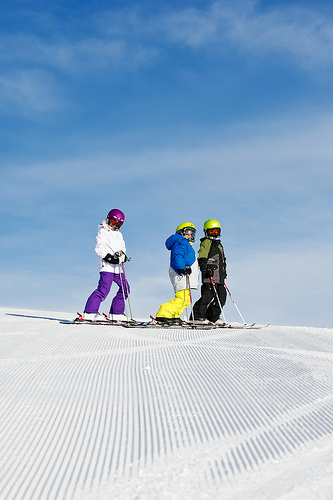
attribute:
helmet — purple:
[108, 209, 125, 229]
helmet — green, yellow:
[204, 219, 223, 233]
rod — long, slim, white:
[117, 261, 130, 324]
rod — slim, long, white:
[123, 267, 142, 319]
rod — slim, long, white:
[184, 275, 196, 327]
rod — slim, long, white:
[211, 276, 230, 325]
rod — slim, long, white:
[223, 280, 252, 325]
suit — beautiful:
[191, 237, 227, 321]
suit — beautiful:
[154, 233, 199, 319]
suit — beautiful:
[83, 222, 130, 318]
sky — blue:
[0, 0, 332, 330]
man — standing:
[189, 219, 228, 323]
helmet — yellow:
[179, 221, 197, 235]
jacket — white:
[95, 222, 129, 274]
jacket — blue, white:
[164, 233, 198, 275]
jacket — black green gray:
[197, 235, 229, 284]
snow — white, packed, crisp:
[0, 308, 333, 499]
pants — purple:
[83, 273, 130, 315]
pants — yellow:
[156, 290, 194, 321]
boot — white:
[85, 312, 104, 320]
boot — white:
[107, 313, 128, 321]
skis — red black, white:
[75, 314, 269, 331]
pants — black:
[188, 282, 228, 320]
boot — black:
[155, 317, 171, 325]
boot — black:
[176, 317, 188, 325]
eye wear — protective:
[110, 219, 121, 228]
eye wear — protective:
[185, 229, 194, 234]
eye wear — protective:
[208, 228, 219, 232]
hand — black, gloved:
[104, 253, 119, 265]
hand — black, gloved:
[181, 267, 193, 275]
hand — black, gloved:
[204, 269, 214, 279]